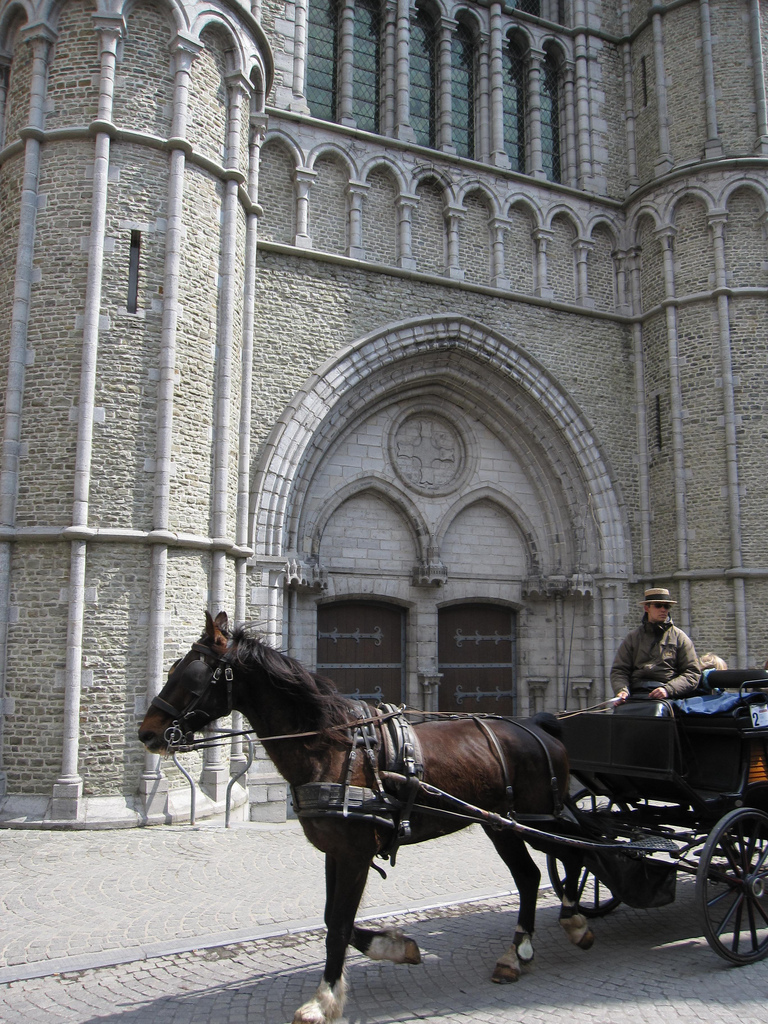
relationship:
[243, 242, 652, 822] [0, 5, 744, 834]
wall on side of building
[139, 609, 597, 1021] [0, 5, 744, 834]
horse in front of building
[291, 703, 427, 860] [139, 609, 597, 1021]
harness worn by horse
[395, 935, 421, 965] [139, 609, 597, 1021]
hoof belongs to horse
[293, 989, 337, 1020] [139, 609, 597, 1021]
hoof belongs to horse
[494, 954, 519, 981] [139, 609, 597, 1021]
hoof belongs to horse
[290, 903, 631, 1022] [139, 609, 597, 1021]
hoofs belongs to horse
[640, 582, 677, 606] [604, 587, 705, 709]
hat worn by human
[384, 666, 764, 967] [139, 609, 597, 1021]
carriage pulled by horse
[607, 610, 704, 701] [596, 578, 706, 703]
jacket worn by human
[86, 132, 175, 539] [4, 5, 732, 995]
wall on side of building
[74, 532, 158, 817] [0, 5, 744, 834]
wall on side of building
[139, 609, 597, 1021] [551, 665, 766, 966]
horse pulling carriage